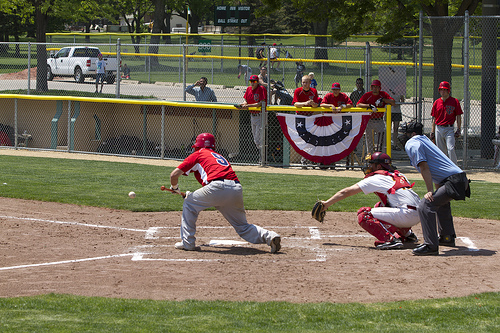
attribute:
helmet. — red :
[190, 127, 215, 149]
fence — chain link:
[1, 39, 498, 165]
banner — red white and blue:
[272, 106, 374, 161]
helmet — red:
[185, 127, 221, 152]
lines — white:
[129, 219, 326, 276]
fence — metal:
[1, 10, 499, 168]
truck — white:
[46, 42, 123, 85]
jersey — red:
[176, 142, 242, 192]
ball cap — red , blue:
[330, 78, 342, 90]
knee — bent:
[233, 220, 261, 242]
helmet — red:
[196, 129, 217, 151]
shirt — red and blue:
[177, 146, 241, 186]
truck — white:
[64, 31, 132, 91]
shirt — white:
[349, 171, 427, 213]